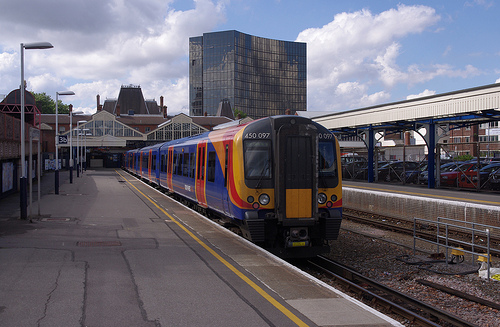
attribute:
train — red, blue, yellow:
[118, 113, 346, 260]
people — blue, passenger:
[140, 110, 352, 255]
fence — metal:
[411, 212, 498, 284]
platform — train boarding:
[0, 167, 405, 325]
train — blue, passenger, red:
[122, 103, 359, 235]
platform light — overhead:
[23, 42, 53, 50]